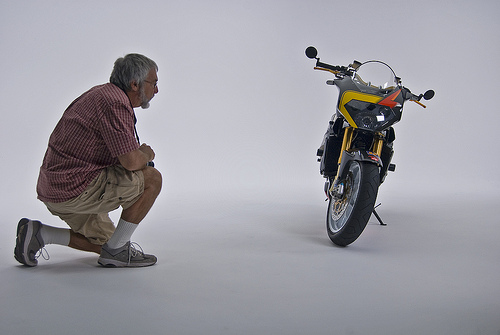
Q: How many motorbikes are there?
A: One.